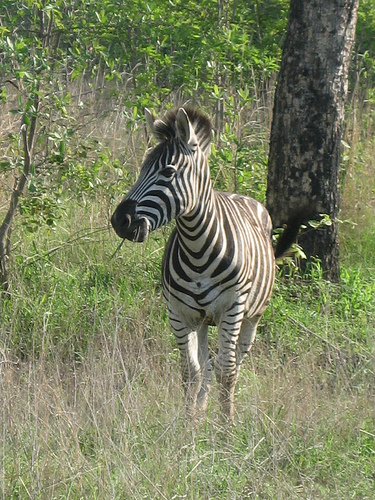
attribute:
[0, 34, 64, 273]
tree — green, distant, small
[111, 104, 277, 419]
zebra — striped, staring, young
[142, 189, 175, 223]
stripe — black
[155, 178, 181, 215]
stripe — black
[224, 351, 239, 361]
stripe — black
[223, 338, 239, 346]
stripe — black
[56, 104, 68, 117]
leaf — green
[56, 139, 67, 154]
leaf — green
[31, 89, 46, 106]
leaf — green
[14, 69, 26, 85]
leaf — green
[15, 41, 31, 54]
leaf — green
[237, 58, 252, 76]
leaf — green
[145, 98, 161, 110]
leaf — green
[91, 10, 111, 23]
leaf — green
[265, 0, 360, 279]
tree — old, distant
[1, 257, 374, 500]
grass — dead, tall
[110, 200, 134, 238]
snout — black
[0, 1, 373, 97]
foliage — dense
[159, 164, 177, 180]
eye — glazed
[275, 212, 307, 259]
tail — black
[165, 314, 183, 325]
stripe — black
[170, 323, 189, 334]
stripe — black